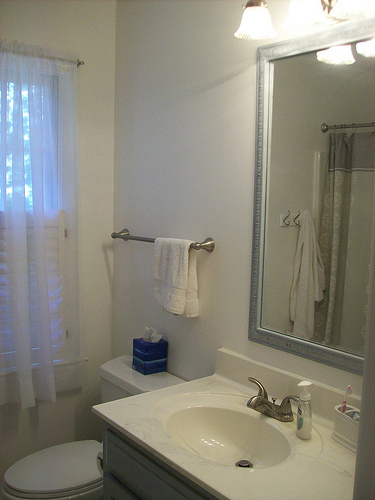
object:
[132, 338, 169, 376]
box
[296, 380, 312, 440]
bottle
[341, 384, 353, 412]
toothbrush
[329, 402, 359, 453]
holder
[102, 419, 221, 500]
commode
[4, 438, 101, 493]
lid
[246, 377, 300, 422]
faucet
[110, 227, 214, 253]
bar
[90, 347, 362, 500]
sink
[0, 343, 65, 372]
shutters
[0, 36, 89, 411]
shears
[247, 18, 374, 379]
mirror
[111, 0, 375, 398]
wall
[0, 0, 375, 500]
bathroom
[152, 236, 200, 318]
towel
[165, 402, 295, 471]
basin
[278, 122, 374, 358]
reflection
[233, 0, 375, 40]
lighting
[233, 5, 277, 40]
shade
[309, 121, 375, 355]
shower curtain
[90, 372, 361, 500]
countertop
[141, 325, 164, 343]
tissue